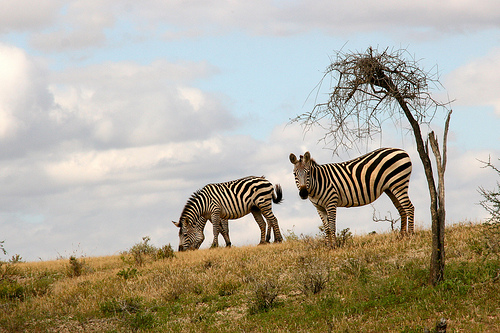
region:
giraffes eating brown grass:
[171, 175, 289, 261]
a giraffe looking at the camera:
[281, 139, 428, 251]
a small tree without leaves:
[316, 41, 461, 294]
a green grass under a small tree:
[373, 267, 428, 302]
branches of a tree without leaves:
[328, 47, 399, 104]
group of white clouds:
[12, 67, 162, 164]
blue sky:
[237, 50, 280, 81]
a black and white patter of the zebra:
[357, 164, 391, 186]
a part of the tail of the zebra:
[271, 180, 286, 207]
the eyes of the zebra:
[287, 169, 313, 179]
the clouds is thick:
[63, 68, 160, 150]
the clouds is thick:
[60, 124, 212, 219]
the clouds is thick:
[76, 81, 183, 176]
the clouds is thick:
[130, 145, 211, 205]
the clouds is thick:
[109, 87, 240, 225]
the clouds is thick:
[102, 104, 154, 159]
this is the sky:
[245, 49, 279, 107]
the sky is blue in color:
[232, 40, 277, 126]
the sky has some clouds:
[79, 66, 147, 147]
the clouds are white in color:
[120, 96, 170, 173]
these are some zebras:
[170, 147, 427, 239]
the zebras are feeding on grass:
[171, 207, 220, 246]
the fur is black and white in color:
[330, 170, 362, 190]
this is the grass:
[311, 281, 407, 331]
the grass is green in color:
[343, 300, 398, 318]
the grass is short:
[341, 276, 391, 302]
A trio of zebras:
[167, 140, 405, 251]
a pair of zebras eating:
[166, 160, 291, 261]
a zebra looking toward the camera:
[286, 144, 441, 238]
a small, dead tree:
[333, 43, 464, 300]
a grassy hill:
[7, 222, 497, 331]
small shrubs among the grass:
[123, 238, 173, 268]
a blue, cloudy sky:
[2, 0, 491, 258]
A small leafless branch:
[368, 201, 413, 232]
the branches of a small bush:
[473, 152, 498, 243]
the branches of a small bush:
[0, 229, 24, 313]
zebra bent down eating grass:
[175, 176, 282, 246]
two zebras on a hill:
[172, 147, 412, 249]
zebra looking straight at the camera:
[290, 144, 412, 235]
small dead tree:
[289, 48, 444, 283]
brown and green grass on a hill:
[1, 224, 493, 331]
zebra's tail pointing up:
[270, 180, 285, 204]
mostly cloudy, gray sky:
[1, 1, 498, 259]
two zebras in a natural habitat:
[175, 142, 412, 246]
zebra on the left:
[171, 171, 281, 242]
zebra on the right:
[290, 147, 414, 235]